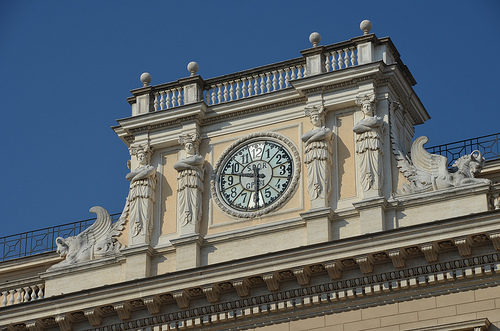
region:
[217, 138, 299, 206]
black and white clock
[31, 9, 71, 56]
white clouds in blue sky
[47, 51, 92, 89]
white clouds in blue sky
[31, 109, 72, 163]
white clouds in blue sky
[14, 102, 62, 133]
white clouds in blue sky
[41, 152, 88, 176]
white clouds in blue sky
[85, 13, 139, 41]
white clouds in blue sky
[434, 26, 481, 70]
white clouds in blue sky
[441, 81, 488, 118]
white clouds in blue sky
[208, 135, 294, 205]
The clock has a white face.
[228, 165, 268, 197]
The hands are black.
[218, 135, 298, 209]
The numbers are black.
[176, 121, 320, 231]
The clock is on the wall.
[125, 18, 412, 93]
The balcony is on top.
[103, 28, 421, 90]
The pillars are brown.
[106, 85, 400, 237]
The wall is tan.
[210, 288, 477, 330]
The building is brick.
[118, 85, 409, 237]
Statues are on the building.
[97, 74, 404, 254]
The statues are next to the clock.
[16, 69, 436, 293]
this buliding is classical architechure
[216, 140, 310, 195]
this is a clock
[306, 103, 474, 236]
these are statues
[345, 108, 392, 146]
the statue has it's arms cross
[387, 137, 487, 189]
this is a griffin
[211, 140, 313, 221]
the clock is blue and white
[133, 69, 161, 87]
the ledge has cement balls on it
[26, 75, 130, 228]
the weather is very clear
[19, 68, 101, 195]
the sky is very light blue here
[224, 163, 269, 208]
the clock arms are black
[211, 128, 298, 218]
ornate clock reads 9:30 am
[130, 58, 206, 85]
concrete globes on left side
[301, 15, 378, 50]
concrete globes on right side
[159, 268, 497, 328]
beige bricks of the building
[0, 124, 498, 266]
metal decorative railing in back of building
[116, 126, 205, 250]
two statues standing next to clock on left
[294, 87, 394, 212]
two statues standing on the right of clock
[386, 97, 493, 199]
statue of a winged creature on right side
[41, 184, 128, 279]
statue of winged creature facing away from clock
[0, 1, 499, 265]
clock tower against clear blue sky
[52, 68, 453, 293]
the top part of a building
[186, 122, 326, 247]
a clock tower on the building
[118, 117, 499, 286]
the building is tan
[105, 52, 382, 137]
this building is made of stone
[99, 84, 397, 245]
statues on bothsides of the clock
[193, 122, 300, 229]
the time is 5:47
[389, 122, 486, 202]
a statue of a winged creature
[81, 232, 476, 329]
the ledge of a roof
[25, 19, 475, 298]
a clear sky over the structure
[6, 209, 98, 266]
railing on the roof